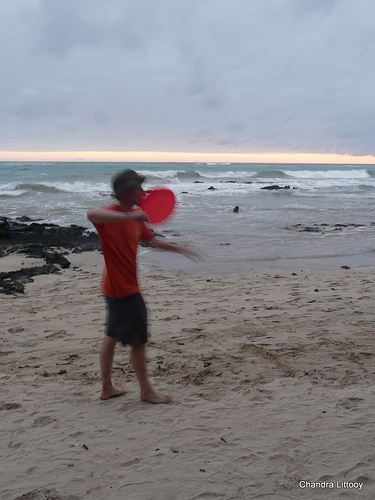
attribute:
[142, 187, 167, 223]
frisbee — blurred, red, thrown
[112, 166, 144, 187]
hat — worn, floppy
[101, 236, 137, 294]
shirt — orange, short sleeve, red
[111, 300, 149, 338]
pants — grey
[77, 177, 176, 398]
man — shoeless, standing, without shoes, blurry, playing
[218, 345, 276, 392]
sand — tan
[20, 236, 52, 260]
rocks — black, rounded, protruding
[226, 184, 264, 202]
water — rocky, choppy, blue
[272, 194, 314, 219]
waves — big, crashing, rolling, rough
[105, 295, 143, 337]
shorts — dark, gray, blue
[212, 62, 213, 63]
sky — cloudy, overcast, clear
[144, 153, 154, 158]
sunlight — yellow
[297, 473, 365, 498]
watermark — bottom